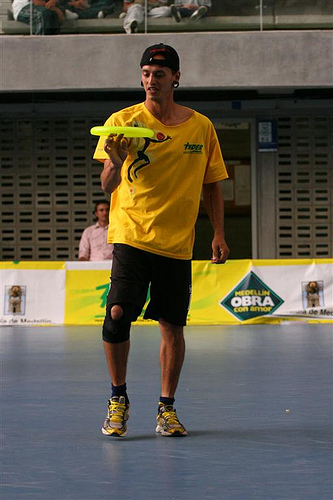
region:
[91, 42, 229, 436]
standing man with frisbee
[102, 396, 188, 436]
sneakers with yellow laces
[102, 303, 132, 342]
black brace on knee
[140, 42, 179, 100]
backwards hat on head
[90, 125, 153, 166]
yellow frisbee on fingers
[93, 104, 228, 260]
short sleeve yellow tee shirt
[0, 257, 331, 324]
wall with multiple logos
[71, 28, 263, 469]
this is a man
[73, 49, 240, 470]
man doing a trick with frisbee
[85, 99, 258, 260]
man wearing a yellow shirt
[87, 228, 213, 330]
man wearing black shorts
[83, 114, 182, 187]
frisbee is neon green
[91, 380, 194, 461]
man wearing yellow shoes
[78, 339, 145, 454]
man has foot off the groun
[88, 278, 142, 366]
man wearing a knee support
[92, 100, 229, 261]
a yellow short sleeve t-shrit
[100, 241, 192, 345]
a pair of black shorts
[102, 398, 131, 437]
a black white and yellow tennis shoe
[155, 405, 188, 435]
a black white and yellow tennis shoe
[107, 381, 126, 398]
a short blue sock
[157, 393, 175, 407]
a short blue sock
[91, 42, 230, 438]
a man playing frisbee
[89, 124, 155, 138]
a bright yellow frisbee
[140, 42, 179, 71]
the back of a black cap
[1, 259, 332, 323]
a long stadium banner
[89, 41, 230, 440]
a man balancing a frisbee on his finger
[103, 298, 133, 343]
a man's knee brace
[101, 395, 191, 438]
a man's tennis shoes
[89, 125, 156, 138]
a yellow lightweight frisbee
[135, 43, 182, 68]
a man's baseball cap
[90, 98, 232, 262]
a man's bright yellow t-shirt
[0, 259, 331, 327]
an advertising banner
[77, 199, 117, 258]
a man standing behind a banner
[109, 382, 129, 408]
a man's dark colored sock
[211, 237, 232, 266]
a man's left hand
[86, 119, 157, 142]
The frisbe is yellow.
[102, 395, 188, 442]
The man is wearing yellow and gray tennis shoes.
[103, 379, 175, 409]
The man is wearing blue socks.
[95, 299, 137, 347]
The man is wearing a knee brace.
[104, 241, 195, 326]
The man is wearing black shorts.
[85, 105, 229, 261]
The man is wearing a yellow shirt.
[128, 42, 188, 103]
The man is wearing a hat.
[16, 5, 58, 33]
The man is the background is wearing blue jeans.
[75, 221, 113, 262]
The man in the background is wearing a pink shirt.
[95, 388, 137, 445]
yellow shoe on man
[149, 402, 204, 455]
yellow shoe on man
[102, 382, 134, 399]
black sock on man